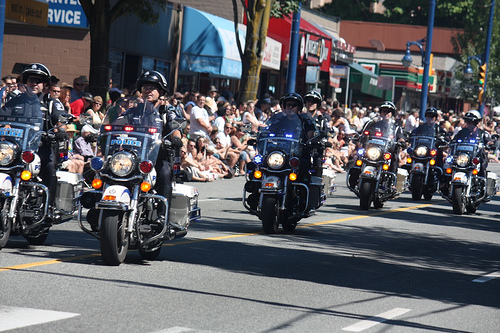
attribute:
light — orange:
[138, 178, 151, 192]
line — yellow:
[171, 223, 261, 253]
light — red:
[137, 159, 157, 175]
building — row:
[109, 2, 283, 96]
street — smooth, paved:
[0, 272, 498, 331]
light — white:
[240, 142, 304, 174]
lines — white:
[352, 287, 410, 332]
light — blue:
[89, 155, 106, 172]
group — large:
[4, 58, 499, 257]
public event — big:
[9, 45, 485, 312]